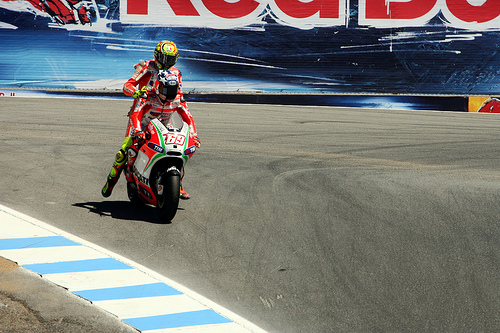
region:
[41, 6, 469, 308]
Picture is taken outside.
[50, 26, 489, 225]
Picture is taken during the day.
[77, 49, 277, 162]
Two people are on a motorcycle.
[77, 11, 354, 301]
Picture is taken in a race track.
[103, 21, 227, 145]
Both people are wearing motorcycle helmets.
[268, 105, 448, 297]
The pavement is grey.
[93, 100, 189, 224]
The motorcycle is red, white and green.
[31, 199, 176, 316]
The side of the track is blue and white.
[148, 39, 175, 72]
The motorcyclist is wearing a yellow and red helmet.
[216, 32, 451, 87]
The back of the track wall is painted blue.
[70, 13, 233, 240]
men riding pillion on a racing bike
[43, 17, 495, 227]
a motorcycle track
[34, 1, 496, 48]
a sign for red bull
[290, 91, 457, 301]
pavement with tire tracks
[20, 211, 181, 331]
a race boundary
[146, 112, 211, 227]
a racing bike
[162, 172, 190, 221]
very smooth track tire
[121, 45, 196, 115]
2 men in helmets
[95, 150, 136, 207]
a racing boot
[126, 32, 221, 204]
2 men wearing racing gear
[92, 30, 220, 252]
Both motorcyclists and motorcycle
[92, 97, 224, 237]
motorcycle with 69 on it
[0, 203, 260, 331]
Blue and white stripes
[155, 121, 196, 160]
69 on the motorcycle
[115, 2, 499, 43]
bottom of redbull logo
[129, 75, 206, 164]
driver of motorcycle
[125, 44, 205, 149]
passenger of motorcycle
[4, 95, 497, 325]
asphalt of motorcycle track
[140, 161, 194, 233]
Front wheel on the motorcycle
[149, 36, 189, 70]
Yellow multicolored helmet on passenger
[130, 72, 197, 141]
a person on a motorbike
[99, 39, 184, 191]
a person on a motorbike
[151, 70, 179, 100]
a colored helmet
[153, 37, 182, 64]
a colored helmet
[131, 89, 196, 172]
a colored suit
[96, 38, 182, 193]
a colored suit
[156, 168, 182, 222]
a black motorbike wheel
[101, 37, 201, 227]
two people on a motorbike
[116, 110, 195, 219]
a colored motorbike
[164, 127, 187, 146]
a number on a motorbike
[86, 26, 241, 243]
two people sitting on a motorcycle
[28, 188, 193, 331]
guiding lines painted on the street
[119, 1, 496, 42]
signage on the background wall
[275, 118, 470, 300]
skid marks on the road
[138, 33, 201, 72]
a multicolored safety helmet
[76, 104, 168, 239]
protective riding knee pads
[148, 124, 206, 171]
a red lettered racing letter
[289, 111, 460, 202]
road texture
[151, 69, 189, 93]
a white starred racing helmet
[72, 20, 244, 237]
a motorcycling racing duo